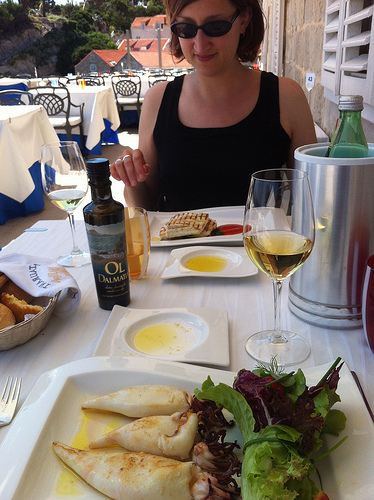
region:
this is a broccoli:
[239, 423, 291, 492]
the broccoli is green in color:
[242, 431, 293, 496]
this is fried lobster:
[60, 457, 182, 491]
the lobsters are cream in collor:
[68, 417, 185, 494]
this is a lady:
[128, 0, 291, 126]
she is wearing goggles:
[169, 15, 233, 40]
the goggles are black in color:
[171, 14, 231, 38]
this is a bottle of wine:
[87, 158, 119, 307]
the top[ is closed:
[84, 153, 112, 179]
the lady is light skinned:
[215, 73, 244, 101]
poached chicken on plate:
[63, 384, 207, 498]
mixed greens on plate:
[199, 357, 346, 498]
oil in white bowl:
[125, 311, 210, 354]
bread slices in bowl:
[0, 279, 44, 328]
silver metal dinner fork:
[1, 374, 22, 427]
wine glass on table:
[247, 169, 313, 365]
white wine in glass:
[245, 228, 310, 281]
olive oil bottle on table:
[85, 158, 132, 307]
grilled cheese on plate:
[161, 209, 214, 236]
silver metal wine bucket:
[291, 142, 372, 331]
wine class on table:
[244, 168, 316, 365]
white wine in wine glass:
[245, 229, 313, 280]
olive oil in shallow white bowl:
[185, 254, 227, 271]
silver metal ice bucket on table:
[288, 140, 372, 328]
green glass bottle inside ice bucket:
[324, 93, 370, 157]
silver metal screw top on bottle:
[338, 95, 362, 107]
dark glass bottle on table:
[82, 157, 131, 309]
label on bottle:
[84, 218, 129, 305]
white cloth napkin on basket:
[0, 252, 82, 319]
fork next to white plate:
[0, 374, 23, 429]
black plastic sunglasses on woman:
[173, 6, 245, 44]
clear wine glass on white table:
[243, 169, 318, 362]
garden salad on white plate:
[224, 357, 351, 496]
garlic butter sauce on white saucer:
[122, 308, 206, 356]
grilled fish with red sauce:
[150, 213, 240, 242]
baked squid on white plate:
[66, 385, 218, 497]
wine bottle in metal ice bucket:
[294, 94, 370, 326]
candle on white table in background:
[77, 79, 85, 91]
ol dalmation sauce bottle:
[85, 156, 130, 312]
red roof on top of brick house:
[74, 47, 126, 69]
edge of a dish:
[26, 437, 55, 473]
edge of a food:
[57, 440, 82, 488]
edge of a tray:
[324, 440, 336, 466]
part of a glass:
[272, 342, 293, 384]